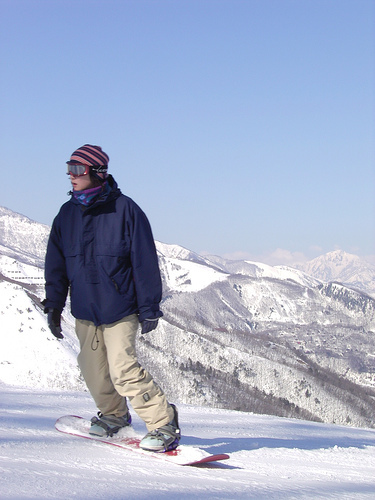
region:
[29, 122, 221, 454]
man riding snow board on hill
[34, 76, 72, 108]
white clouds in blue sky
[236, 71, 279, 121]
white clouds in blue sky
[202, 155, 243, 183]
white clouds in blue sky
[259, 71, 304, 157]
white clouds in blue sky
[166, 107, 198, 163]
white clouds in blue sky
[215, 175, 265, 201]
white clouds in blue sky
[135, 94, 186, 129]
white clouds in blue sky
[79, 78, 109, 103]
white clouds in blue sky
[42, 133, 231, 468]
snowboarder on top of snowy slope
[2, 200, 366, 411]
snow covered ridges, slopes, hills and cliffs behind snowboarder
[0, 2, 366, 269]
clear blue sky behind snowboarder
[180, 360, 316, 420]
triangle of trees below slope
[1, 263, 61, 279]
row of squares to person's side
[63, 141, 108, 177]
pink, red and black striped cap over head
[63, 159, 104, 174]
red goggles with dark lenses and headband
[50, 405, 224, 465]
curved red snowboard covered with snow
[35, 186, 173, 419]
scarf in dark-blue jacket over tan pants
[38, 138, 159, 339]
skateboarder looking to side with hands down and a bent knee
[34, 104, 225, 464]
a man is on the snow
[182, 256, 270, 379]
the snow is white in colour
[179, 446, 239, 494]
the skateboard is red in colour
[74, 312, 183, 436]
the pant is brown in colour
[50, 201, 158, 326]
the jacket is blue in colour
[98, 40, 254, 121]
the sky is blue in colour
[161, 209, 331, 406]
the landscape is mountainous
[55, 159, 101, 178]
the man has goggles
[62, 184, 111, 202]
he has a scarf on the neck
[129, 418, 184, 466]
the shoes are grey in colour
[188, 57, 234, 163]
Part of the blue sky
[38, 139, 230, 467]
A person snowboarding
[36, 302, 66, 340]
The right hand of the person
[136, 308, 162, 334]
The left hand of the person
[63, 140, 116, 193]
The head of the person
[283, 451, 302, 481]
Part of the white snow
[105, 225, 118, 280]
Part of the blue jacket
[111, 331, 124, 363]
Part of the person's pants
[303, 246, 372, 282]
A snowy hill in distance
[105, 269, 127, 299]
The left pocket of the jacket